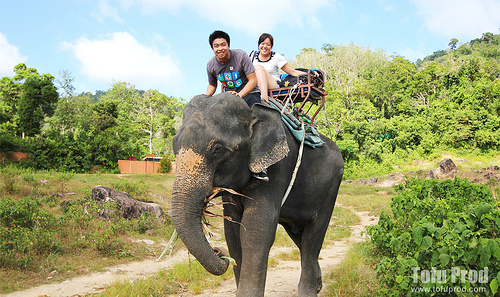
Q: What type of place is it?
A: It is a path.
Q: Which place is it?
A: It is a path.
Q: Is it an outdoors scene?
A: Yes, it is outdoors.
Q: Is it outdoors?
A: Yes, it is outdoors.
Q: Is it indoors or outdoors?
A: It is outdoors.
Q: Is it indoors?
A: No, it is outdoors.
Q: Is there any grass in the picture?
A: Yes, there is grass.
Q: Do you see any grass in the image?
A: Yes, there is grass.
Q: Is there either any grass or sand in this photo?
A: Yes, there is grass.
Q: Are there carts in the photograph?
A: No, there are no carts.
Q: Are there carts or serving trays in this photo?
A: No, there are no carts or serving trays.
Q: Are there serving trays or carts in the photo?
A: No, there are no carts or serving trays.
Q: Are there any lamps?
A: No, there are no lamps.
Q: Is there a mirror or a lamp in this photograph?
A: No, there are no lamps or mirrors.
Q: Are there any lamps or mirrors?
A: No, there are no lamps or mirrors.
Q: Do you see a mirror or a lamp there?
A: No, there are no lamps or mirrors.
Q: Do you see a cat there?
A: No, there are no cats.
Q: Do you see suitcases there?
A: No, there are no suitcases.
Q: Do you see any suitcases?
A: No, there are no suitcases.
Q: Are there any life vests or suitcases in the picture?
A: No, there are no suitcases or life vests.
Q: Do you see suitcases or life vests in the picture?
A: No, there are no suitcases or life vests.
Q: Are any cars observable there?
A: No, there are no cars.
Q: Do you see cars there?
A: No, there are no cars.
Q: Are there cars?
A: No, there are no cars.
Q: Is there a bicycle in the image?
A: No, there are no bicycles.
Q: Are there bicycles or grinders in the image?
A: No, there are no bicycles or grinders.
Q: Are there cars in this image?
A: No, there are no cars.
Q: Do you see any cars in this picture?
A: No, there are no cars.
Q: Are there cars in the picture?
A: No, there are no cars.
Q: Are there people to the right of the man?
A: Yes, there is a person to the right of the man.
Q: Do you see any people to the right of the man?
A: Yes, there is a person to the right of the man.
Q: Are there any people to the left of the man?
A: No, the person is to the right of the man.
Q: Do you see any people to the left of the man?
A: No, the person is to the right of the man.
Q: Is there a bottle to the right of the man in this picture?
A: No, there is a person to the right of the man.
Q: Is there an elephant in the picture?
A: Yes, there is an elephant.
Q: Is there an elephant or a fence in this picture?
A: Yes, there is an elephant.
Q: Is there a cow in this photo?
A: No, there are no cows.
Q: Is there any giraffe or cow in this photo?
A: No, there are no cows or giraffes.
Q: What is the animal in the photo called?
A: The animal is an elephant.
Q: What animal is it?
A: The animal is an elephant.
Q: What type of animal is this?
A: This is an elephant.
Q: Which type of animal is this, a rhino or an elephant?
A: This is an elephant.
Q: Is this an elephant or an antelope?
A: This is an elephant.